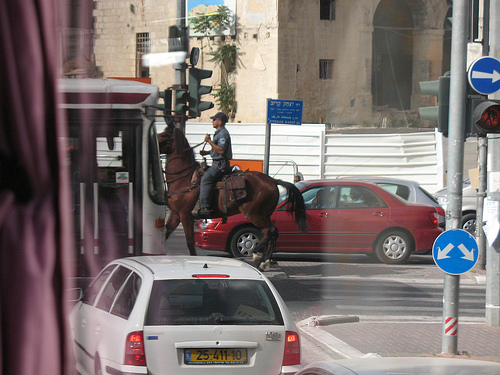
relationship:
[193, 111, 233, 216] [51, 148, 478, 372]
officer in traffic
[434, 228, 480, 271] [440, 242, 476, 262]
sign with arrows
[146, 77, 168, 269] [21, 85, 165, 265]
front of bus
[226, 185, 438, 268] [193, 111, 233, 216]
car behind officer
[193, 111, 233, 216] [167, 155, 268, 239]
officer on horse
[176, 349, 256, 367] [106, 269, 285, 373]
license plate on car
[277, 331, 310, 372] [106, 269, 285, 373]
light on car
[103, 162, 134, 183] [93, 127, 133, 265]
sticker on window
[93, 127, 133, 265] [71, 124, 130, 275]
window of door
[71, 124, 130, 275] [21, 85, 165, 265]
door of bus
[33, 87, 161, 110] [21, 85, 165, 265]
stripe on bus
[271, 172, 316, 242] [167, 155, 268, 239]
tail of horse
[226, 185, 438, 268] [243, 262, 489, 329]
car on road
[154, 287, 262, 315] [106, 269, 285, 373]
window of car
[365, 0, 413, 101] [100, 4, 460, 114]
opening of building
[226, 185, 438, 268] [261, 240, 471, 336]
car in street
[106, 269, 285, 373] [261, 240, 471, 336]
car in street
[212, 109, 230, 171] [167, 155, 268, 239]
officer on horse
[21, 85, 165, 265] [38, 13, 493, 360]
bus in intersection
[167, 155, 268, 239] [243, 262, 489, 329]
horse in road